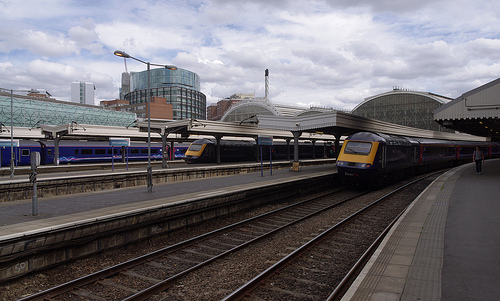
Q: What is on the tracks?
A: Trains.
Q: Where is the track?
A: Under the train.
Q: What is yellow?
A: Train.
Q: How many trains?
A: Two.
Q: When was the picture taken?
A: Daytime.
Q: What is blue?
A: Sky.